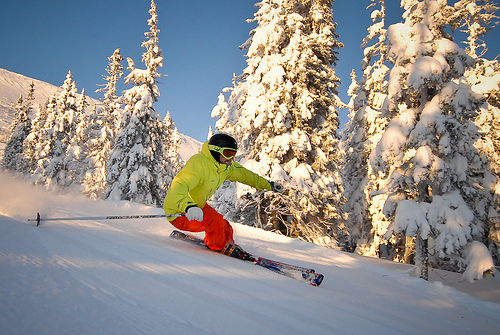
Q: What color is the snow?
A: White.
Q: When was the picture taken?
A: Daytime.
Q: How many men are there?
A: One.